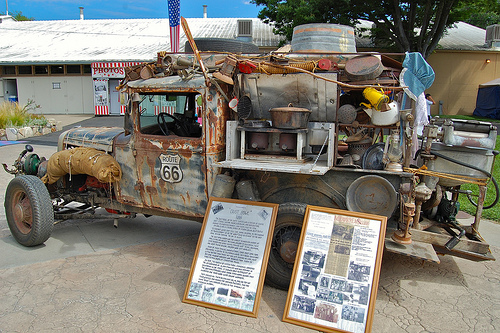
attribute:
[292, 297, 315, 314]
photo — old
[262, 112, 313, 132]
pot — rusty, old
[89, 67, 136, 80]
sign — white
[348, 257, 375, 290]
photo — old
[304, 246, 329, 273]
photo — old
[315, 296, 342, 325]
photo — old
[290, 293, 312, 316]
photo — old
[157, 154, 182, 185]
sign — black, white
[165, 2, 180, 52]
flag — american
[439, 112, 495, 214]
grass — green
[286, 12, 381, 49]
bucket — metal, grey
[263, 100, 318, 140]
pot — metal, rusted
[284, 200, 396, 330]
frame — wooden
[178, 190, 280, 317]
frame — wooden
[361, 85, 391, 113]
coffeepot — yellow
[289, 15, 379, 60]
basin — wash basin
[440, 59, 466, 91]
wall — stucco, tan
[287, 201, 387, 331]
collage — framed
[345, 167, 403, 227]
pot — metal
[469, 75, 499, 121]
tent — blue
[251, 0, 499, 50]
leaves — green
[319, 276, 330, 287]
photo — old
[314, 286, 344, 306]
photo — old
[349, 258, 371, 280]
photo — old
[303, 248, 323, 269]
photo — old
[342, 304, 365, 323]
photo — old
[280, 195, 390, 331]
frame — wooden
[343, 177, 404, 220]
bucket — old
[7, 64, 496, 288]
truck — rusty